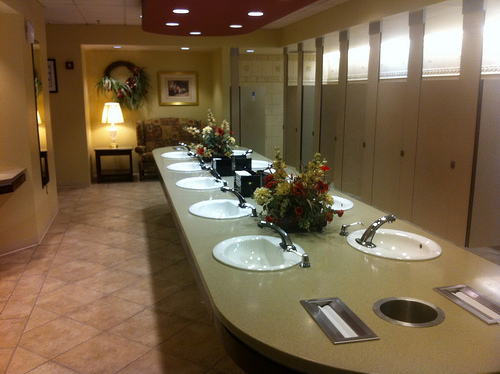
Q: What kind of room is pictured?
A: It is a bathroom.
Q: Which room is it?
A: It is a bathroom.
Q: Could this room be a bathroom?
A: Yes, it is a bathroom.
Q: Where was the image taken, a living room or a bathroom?
A: It was taken at a bathroom.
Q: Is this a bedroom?
A: No, it is a bathroom.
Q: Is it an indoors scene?
A: Yes, it is indoors.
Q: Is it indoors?
A: Yes, it is indoors.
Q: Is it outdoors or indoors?
A: It is indoors.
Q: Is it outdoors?
A: No, it is indoors.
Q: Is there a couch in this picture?
A: Yes, there is a couch.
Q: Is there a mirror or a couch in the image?
A: Yes, there is a couch.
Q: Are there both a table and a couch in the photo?
A: Yes, there are both a couch and a table.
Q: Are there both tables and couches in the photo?
A: Yes, there are both a couch and a table.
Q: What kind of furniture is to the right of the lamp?
A: The piece of furniture is a couch.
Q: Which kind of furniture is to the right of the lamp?
A: The piece of furniture is a couch.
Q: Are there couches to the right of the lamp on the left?
A: Yes, there is a couch to the right of the lamp.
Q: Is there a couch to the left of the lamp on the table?
A: No, the couch is to the right of the lamp.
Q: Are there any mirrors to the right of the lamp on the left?
A: No, there is a couch to the right of the lamp.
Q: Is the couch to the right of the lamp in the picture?
A: Yes, the couch is to the right of the lamp.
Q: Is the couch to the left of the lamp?
A: No, the couch is to the right of the lamp.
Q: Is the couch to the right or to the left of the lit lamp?
A: The couch is to the right of the lamp.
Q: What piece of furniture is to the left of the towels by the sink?
A: The piece of furniture is a couch.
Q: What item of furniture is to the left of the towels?
A: The piece of furniture is a couch.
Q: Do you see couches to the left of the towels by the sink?
A: Yes, there is a couch to the left of the towels.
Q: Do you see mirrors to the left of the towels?
A: No, there is a couch to the left of the towels.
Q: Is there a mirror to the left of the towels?
A: No, there is a couch to the left of the towels.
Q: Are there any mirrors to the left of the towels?
A: No, there is a couch to the left of the towels.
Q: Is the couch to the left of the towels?
A: Yes, the couch is to the left of the towels.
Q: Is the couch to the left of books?
A: No, the couch is to the left of the towels.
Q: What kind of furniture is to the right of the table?
A: The piece of furniture is a couch.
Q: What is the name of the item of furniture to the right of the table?
A: The piece of furniture is a couch.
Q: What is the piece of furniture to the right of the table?
A: The piece of furniture is a couch.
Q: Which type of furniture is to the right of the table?
A: The piece of furniture is a couch.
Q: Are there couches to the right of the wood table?
A: Yes, there is a couch to the right of the table.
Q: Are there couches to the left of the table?
A: No, the couch is to the right of the table.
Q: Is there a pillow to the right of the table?
A: No, there is a couch to the right of the table.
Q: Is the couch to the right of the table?
A: Yes, the couch is to the right of the table.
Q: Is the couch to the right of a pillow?
A: No, the couch is to the right of the table.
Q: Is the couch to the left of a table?
A: No, the couch is to the right of a table.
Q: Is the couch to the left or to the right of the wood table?
A: The couch is to the right of the table.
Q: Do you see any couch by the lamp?
A: Yes, there is a couch by the lamp.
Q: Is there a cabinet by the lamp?
A: No, there is a couch by the lamp.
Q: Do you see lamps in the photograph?
A: Yes, there is a lamp.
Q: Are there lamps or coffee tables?
A: Yes, there is a lamp.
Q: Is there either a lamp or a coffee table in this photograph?
A: Yes, there is a lamp.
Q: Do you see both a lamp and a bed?
A: No, there is a lamp but no beds.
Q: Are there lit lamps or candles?
A: Yes, there is a lit lamp.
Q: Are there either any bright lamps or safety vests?
A: Yes, there is a bright lamp.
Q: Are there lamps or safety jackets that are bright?
A: Yes, the lamp is bright.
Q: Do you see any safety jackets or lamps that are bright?
A: Yes, the lamp is bright.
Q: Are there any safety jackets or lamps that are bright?
A: Yes, the lamp is bright.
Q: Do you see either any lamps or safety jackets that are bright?
A: Yes, the lamp is bright.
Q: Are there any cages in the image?
A: No, there are no cages.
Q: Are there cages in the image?
A: No, there are no cages.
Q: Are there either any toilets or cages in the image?
A: No, there are no cages or toilets.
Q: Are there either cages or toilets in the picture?
A: No, there are no cages or toilets.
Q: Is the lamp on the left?
A: Yes, the lamp is on the left of the image.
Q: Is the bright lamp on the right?
A: No, the lamp is on the left of the image.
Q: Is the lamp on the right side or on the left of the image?
A: The lamp is on the left of the image.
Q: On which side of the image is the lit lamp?
A: The lamp is on the left of the image.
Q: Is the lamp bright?
A: Yes, the lamp is bright.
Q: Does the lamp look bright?
A: Yes, the lamp is bright.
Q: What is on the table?
A: The lamp is on the table.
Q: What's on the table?
A: The lamp is on the table.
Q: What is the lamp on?
A: The lamp is on the table.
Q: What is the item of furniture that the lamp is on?
A: The piece of furniture is a table.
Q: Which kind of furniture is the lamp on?
A: The lamp is on the table.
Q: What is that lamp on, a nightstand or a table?
A: The lamp is on a table.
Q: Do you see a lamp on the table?
A: Yes, there is a lamp on the table.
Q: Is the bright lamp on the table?
A: Yes, the lamp is on the table.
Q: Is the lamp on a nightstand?
A: No, the lamp is on the table.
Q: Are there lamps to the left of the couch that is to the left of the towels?
A: Yes, there is a lamp to the left of the couch.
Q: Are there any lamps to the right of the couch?
A: No, the lamp is to the left of the couch.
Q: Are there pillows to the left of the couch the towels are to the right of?
A: No, there is a lamp to the left of the couch.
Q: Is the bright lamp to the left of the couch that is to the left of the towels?
A: Yes, the lamp is to the left of the couch.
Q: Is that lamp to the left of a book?
A: No, the lamp is to the left of the couch.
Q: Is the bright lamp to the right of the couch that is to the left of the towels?
A: No, the lamp is to the left of the couch.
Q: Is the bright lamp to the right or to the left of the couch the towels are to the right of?
A: The lamp is to the left of the couch.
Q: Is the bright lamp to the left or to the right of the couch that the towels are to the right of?
A: The lamp is to the left of the couch.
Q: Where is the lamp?
A: The lamp is in the bathroom.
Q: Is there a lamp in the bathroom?
A: Yes, there is a lamp in the bathroom.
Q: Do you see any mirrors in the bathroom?
A: No, there is a lamp in the bathroom.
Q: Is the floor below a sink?
A: Yes, the floor is below a sink.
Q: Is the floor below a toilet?
A: No, the floor is below a sink.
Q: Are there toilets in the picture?
A: No, there are no toilets.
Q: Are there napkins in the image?
A: No, there are no napkins.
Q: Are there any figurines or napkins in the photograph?
A: No, there are no napkins or figurines.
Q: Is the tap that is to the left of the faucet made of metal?
A: Yes, the faucet is made of metal.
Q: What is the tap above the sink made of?
A: The faucet is made of metal.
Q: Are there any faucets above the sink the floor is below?
A: Yes, there is a faucet above the sink.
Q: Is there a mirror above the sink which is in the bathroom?
A: No, there is a faucet above the sink.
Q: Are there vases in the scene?
A: No, there are no vases.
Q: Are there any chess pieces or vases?
A: No, there are no vases or chess pieces.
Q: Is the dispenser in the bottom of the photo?
A: Yes, the dispenser is in the bottom of the image.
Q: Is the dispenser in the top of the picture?
A: No, the dispenser is in the bottom of the image.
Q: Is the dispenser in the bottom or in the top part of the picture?
A: The dispenser is in the bottom of the image.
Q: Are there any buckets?
A: No, there are no buckets.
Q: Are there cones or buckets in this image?
A: No, there are no buckets or cones.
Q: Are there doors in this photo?
A: Yes, there is a door.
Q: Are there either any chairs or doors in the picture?
A: Yes, there is a door.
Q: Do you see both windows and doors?
A: No, there is a door but no windows.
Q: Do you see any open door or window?
A: Yes, there is an open door.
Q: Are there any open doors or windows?
A: Yes, there is an open door.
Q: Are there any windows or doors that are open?
A: Yes, the door is open.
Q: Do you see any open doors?
A: Yes, there is an open door.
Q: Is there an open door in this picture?
A: Yes, there is an open door.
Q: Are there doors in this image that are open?
A: Yes, there is a door that is open.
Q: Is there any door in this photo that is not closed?
A: Yes, there is a open door.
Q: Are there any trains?
A: No, there are no trains.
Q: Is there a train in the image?
A: No, there are no trains.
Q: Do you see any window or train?
A: No, there are no trains or windows.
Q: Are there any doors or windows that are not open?
A: No, there is a door but it is open.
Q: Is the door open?
A: Yes, the door is open.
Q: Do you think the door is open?
A: Yes, the door is open.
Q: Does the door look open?
A: Yes, the door is open.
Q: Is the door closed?
A: No, the door is open.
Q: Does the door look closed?
A: No, the door is open.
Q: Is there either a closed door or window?
A: No, there is a door but it is open.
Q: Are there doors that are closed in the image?
A: No, there is a door but it is open.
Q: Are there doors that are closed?
A: No, there is a door but it is open.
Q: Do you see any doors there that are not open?
A: No, there is a door but it is open.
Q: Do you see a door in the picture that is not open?
A: No, there is a door but it is open.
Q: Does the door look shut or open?
A: The door is open.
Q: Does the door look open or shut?
A: The door is open.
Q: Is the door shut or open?
A: The door is open.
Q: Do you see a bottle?
A: No, there are no bottles.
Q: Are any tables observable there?
A: Yes, there is a table.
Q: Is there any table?
A: Yes, there is a table.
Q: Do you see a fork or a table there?
A: Yes, there is a table.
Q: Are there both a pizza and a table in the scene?
A: No, there is a table but no pizzas.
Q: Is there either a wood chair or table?
A: Yes, there is a wood table.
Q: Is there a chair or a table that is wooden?
A: Yes, the table is wooden.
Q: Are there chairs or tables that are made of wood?
A: Yes, the table is made of wood.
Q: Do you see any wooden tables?
A: Yes, there is a wood table.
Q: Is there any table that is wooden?
A: Yes, there is a table that is wooden.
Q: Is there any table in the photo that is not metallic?
A: Yes, there is a wooden table.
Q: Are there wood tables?
A: Yes, there is a table that is made of wood.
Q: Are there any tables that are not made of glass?
A: Yes, there is a table that is made of wood.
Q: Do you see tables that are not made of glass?
A: Yes, there is a table that is made of wood.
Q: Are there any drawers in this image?
A: No, there are no drawers.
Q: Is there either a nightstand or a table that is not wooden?
A: No, there is a table but it is wooden.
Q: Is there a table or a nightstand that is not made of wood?
A: No, there is a table but it is made of wood.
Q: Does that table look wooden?
A: Yes, the table is wooden.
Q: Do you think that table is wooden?
A: Yes, the table is wooden.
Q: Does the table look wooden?
A: Yes, the table is wooden.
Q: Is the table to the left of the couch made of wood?
A: Yes, the table is made of wood.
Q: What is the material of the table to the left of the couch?
A: The table is made of wood.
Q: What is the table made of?
A: The table is made of wood.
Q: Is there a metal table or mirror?
A: No, there is a table but it is wooden.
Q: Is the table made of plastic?
A: No, the table is made of wood.